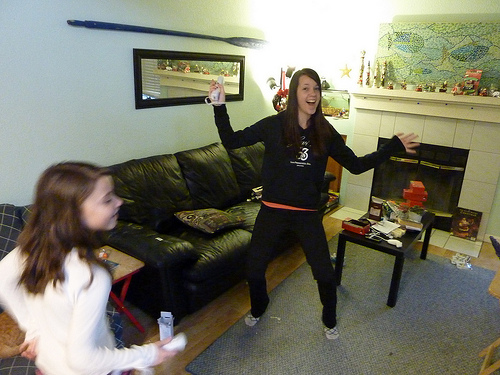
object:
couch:
[94, 141, 337, 326]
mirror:
[140, 58, 241, 101]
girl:
[208, 68, 420, 340]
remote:
[208, 74, 225, 100]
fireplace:
[339, 87, 500, 258]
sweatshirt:
[211, 103, 408, 211]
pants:
[244, 201, 338, 328]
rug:
[300, 345, 429, 375]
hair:
[281, 110, 296, 150]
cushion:
[172, 206, 247, 234]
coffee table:
[331, 200, 436, 308]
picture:
[372, 21, 499, 98]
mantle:
[348, 87, 499, 124]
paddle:
[65, 19, 272, 50]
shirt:
[0, 244, 156, 373]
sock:
[242, 312, 259, 326]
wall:
[0, 50, 123, 123]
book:
[449, 205, 484, 243]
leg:
[331, 238, 347, 286]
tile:
[431, 118, 461, 141]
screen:
[369, 154, 465, 213]